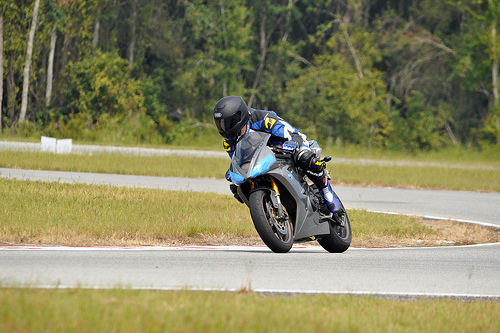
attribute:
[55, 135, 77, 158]
sign — white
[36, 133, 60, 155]
sign — white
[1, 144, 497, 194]
grass — brown, dry, dying, green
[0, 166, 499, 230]
road — curved, curve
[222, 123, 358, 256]
motorcycle — blue, grey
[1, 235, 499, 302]
road — paved, curved, curve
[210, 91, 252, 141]
helmet — black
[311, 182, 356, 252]
tires — black, back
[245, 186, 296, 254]
tires — black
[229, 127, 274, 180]
windshield — clear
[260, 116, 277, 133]
patch — yellow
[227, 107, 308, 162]
jacket — blue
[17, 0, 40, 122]
trunks — skinny, white, grey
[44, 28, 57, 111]
trunks — skinny, white, grey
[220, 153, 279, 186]
stripe — light blue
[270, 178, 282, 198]
pole — orange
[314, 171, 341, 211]
boot — blue, white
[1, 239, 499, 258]
edge — white